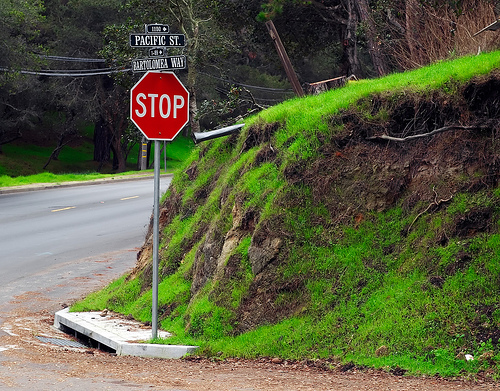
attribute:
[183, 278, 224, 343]
grass — green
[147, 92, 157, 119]
letters — white 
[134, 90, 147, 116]
letters — white 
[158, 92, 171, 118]
letters — white 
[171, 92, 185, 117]
letters — white 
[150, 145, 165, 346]
pole — for street sign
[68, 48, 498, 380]
grass — green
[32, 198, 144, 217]
lines — yellow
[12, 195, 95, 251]
lines — yellow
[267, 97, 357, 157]
grass — green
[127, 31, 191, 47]
pacific street — sign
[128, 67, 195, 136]
stop sign — eight-sided